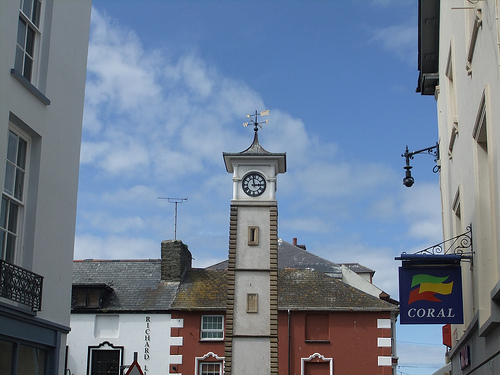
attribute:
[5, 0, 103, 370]
building — white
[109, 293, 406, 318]
balcony — small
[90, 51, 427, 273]
sky — blue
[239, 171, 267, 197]
clock — black and white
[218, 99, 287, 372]
tower — clock, white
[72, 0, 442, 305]
weather — vane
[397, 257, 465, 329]
sign — Coral, colorful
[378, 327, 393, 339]
brick — red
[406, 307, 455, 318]
word — coral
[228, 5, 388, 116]
sky — blue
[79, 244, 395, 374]
building — red, tall, white, brown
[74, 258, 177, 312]
roof — gray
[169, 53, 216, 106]
cloud — white